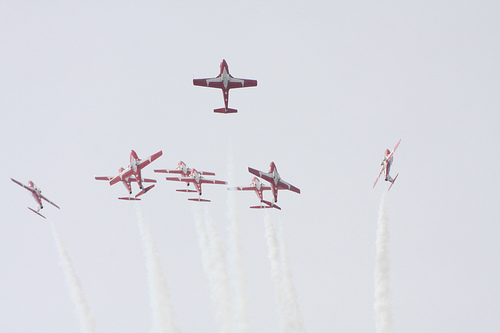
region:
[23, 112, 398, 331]
the planes are leaving white trails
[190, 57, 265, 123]
the plane in the front is red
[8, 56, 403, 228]
the planes are red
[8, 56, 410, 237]
the planes have white accents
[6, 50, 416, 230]
the planes are flying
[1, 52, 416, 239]
nine planes are flying close together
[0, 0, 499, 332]
the sky is bright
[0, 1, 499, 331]
the sky is grey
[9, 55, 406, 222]
the planes are flying high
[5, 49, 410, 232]
the planes are in the sky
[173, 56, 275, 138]
a red and white plane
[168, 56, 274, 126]
a vertical plane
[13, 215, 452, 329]
smoke trails from the planes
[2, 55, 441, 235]
several red and white planes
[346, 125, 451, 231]
a plane in mid roll on the right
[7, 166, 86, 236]
a plane in mid roll on the left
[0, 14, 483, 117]
grey skies behind a plane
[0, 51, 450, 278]
nine planes performing a stunt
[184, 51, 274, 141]
the underside of a red and white plane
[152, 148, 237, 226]
two parallel planes performing a trick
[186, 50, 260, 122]
a plane up in the sky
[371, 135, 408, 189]
a plane up in the sky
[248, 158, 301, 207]
a plane up in the sky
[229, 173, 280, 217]
a plane up in the sky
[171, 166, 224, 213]
a plane up in the sky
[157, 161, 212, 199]
a plane up in the sky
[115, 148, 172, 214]
a plane up in the sky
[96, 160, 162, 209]
a plane up in the sky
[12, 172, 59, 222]
a plane up in the sky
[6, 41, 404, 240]
planes up in the sky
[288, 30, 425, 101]
clear blue sky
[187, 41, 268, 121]
red and white airplane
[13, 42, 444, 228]
group of turbo prop airplanes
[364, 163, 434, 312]
smoke coming from a plane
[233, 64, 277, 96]
red and white airplane wing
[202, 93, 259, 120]
red tail section of a plane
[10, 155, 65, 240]
a plane about to fly upside down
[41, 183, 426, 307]
smoke trails from several planes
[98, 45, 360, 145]
the underside of an airplane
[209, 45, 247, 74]
the prop of an airplane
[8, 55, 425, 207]
Nine planes in the sky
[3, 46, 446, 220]
Jet planes in the sky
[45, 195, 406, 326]
Steam of jet planes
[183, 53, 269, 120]
Red and white jet plane on other of eight palnes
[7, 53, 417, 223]
Red and white jet planes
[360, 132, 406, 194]
Jet plane on the side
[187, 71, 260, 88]
Wings of jet plane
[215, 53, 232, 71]
Cockpit of jet plane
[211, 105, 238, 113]
Stabilizer of jet plane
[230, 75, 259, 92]
Side wing of plane